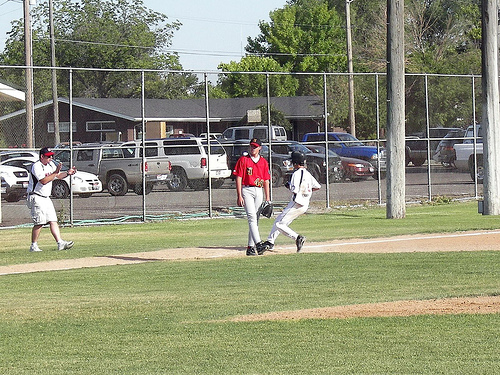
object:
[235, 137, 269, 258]
person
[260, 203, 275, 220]
baseball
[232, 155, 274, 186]
shirt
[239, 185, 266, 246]
pants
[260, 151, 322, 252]
player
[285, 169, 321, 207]
shirt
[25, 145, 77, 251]
man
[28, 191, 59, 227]
shorts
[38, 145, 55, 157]
cap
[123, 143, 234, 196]
car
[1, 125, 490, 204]
parking lot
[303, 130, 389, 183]
truck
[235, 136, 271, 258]
red and white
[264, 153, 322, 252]
white and black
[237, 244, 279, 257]
base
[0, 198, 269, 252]
field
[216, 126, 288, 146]
van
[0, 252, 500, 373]
grass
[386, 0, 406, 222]
pole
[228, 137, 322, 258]
game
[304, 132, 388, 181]
cars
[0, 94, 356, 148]
building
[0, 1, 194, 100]
tree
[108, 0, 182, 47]
leaves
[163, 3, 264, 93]
sky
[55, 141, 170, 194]
truck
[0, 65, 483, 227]
fence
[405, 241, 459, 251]
dirt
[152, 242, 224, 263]
pitcher's mound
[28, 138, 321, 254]
match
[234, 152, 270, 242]
uniform